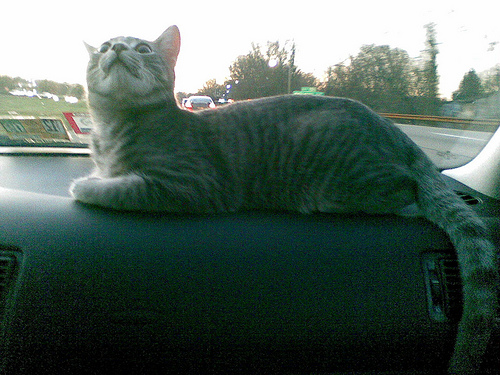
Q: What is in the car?
A: A cat.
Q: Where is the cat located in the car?
A: On top of the front dashboard.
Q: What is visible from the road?
A: Trees.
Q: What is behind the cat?
A: The glass windshield of the vehicle.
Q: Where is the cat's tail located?
A: Near the air vent.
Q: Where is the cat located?
A: On the top of the car.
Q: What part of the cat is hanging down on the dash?
A: Cat's tail.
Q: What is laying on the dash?
A: Cat.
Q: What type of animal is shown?
A: Cat.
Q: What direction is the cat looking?
A: Up.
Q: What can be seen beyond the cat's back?
A: Car.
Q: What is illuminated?
A: Tail lights.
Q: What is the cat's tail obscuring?
A: Air vent.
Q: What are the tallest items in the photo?
A: Trees.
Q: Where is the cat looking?
A: Up.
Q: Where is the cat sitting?
A: Dashboard.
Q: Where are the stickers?
A: Windshield.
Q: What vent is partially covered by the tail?
A: Right side one.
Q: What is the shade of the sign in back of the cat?
A: Green and white.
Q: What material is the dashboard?
A: Plastic.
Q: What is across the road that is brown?
A: Railing.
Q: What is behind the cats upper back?
A: Car.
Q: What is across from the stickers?
A: Houses.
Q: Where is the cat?
A: On the dashboard.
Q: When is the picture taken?
A: The daytime.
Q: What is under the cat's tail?
A: Air conditioner.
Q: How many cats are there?
A: One.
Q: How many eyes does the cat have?
A: Two.